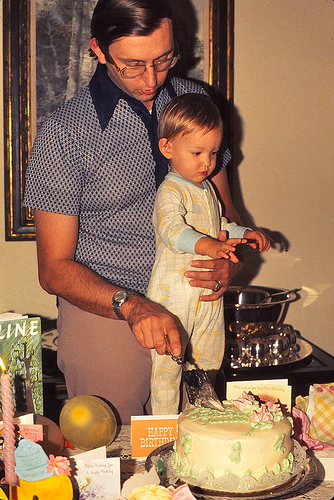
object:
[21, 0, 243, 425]
man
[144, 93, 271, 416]
baby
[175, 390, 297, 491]
cake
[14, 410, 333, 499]
table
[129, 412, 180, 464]
birthday cards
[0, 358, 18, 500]
candle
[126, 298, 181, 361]
right hand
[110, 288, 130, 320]
watch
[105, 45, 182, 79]
glasses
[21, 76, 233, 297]
shirt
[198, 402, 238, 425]
icing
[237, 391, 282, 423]
roses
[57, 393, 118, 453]
balloon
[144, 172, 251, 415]
pajamas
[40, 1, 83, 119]
tree picture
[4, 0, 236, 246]
frame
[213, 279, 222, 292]
ring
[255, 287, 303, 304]
spoon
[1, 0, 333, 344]
wall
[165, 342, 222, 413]
knife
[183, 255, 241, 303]
hand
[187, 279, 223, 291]
finger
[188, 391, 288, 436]
top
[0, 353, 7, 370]
flame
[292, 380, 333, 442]
cloth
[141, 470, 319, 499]
edge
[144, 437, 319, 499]
cake plate